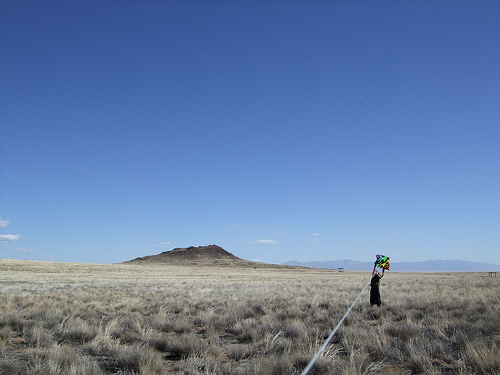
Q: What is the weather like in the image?
A: It is cloudy.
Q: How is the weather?
A: It is cloudy.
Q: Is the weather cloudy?
A: Yes, it is cloudy.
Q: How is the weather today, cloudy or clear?
A: It is cloudy.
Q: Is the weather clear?
A: No, it is cloudy.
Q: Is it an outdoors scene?
A: Yes, it is outdoors.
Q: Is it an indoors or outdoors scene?
A: It is outdoors.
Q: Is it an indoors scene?
A: No, it is outdoors.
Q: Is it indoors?
A: No, it is outdoors.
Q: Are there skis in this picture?
A: No, there are no skis.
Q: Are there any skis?
A: No, there are no skis.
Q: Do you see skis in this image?
A: No, there are no skis.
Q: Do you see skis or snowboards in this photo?
A: No, there are no skis or snowboards.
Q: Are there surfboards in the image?
A: No, there are no surfboards.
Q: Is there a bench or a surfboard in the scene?
A: No, there are no surfboards or benches.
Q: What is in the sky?
A: The clouds are in the sky.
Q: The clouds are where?
A: The clouds are in the sky.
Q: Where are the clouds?
A: The clouds are in the sky.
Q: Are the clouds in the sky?
A: Yes, the clouds are in the sky.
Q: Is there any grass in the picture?
A: Yes, there is grass.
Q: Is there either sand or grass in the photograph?
A: Yes, there is grass.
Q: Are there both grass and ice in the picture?
A: No, there is grass but no ice.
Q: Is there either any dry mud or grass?
A: Yes, there is dry grass.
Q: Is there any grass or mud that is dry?
A: Yes, the grass is dry.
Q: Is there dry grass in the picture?
A: Yes, there is dry grass.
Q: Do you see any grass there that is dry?
A: Yes, there is grass that is dry.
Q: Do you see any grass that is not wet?
A: Yes, there is dry grass.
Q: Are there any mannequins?
A: No, there are no mannequins.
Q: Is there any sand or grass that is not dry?
A: No, there is grass but it is dry.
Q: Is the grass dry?
A: Yes, the grass is dry.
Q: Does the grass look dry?
A: Yes, the grass is dry.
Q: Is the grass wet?
A: No, the grass is dry.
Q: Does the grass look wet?
A: No, the grass is dry.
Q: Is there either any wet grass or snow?
A: No, there is grass but it is dry.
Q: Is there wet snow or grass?
A: No, there is grass but it is dry.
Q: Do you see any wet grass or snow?
A: No, there is grass but it is dry.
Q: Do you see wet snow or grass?
A: No, there is grass but it is dry.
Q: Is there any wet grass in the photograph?
A: No, there is grass but it is dry.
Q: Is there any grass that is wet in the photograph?
A: No, there is grass but it is dry.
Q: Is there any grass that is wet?
A: No, there is grass but it is dry.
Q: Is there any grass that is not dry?
A: No, there is grass but it is dry.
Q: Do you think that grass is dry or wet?
A: The grass is dry.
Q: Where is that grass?
A: The grass is in the field.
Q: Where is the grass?
A: The grass is in the field.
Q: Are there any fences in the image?
A: No, there are no fences.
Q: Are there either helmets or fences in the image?
A: No, there are no fences or helmets.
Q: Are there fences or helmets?
A: No, there are no fences or helmets.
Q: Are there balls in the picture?
A: No, there are no balls.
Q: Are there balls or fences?
A: No, there are no balls or fences.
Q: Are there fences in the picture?
A: No, there are no fences.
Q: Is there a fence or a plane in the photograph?
A: No, there are no fences or airplanes.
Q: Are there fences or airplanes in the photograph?
A: No, there are no fences or airplanes.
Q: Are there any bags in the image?
A: No, there are no bags.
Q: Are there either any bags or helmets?
A: No, there are no bags or helmets.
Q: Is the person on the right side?
A: Yes, the person is on the right of the image.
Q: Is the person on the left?
A: No, the person is on the right of the image.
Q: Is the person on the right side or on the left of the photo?
A: The person is on the right of the image.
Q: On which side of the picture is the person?
A: The person is on the right of the image.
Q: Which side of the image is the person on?
A: The person is on the right of the image.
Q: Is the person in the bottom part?
A: Yes, the person is in the bottom of the image.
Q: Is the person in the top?
A: No, the person is in the bottom of the image.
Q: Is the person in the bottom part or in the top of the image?
A: The person is in the bottom of the image.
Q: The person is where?
A: The person is in the field.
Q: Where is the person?
A: The person is in the field.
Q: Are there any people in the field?
A: Yes, there is a person in the field.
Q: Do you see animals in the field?
A: No, there is a person in the field.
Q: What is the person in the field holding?
A: The person is holding the kite.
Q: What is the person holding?
A: The person is holding the kite.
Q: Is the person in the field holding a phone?
A: No, the person is holding the kite.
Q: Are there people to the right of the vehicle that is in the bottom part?
A: Yes, there is a person to the right of the vehicle.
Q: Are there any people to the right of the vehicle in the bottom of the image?
A: Yes, there is a person to the right of the vehicle.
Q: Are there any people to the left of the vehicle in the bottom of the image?
A: No, the person is to the right of the vehicle.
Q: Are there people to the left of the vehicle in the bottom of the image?
A: No, the person is to the right of the vehicle.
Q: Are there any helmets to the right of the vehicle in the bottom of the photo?
A: No, there is a person to the right of the vehicle.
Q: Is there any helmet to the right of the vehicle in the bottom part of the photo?
A: No, there is a person to the right of the vehicle.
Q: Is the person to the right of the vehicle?
A: Yes, the person is to the right of the vehicle.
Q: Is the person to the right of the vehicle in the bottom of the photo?
A: Yes, the person is to the right of the vehicle.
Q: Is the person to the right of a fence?
A: No, the person is to the right of the vehicle.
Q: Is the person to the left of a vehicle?
A: No, the person is to the right of a vehicle.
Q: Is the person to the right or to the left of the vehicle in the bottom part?
A: The person is to the right of the vehicle.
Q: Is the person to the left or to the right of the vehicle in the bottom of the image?
A: The person is to the right of the vehicle.